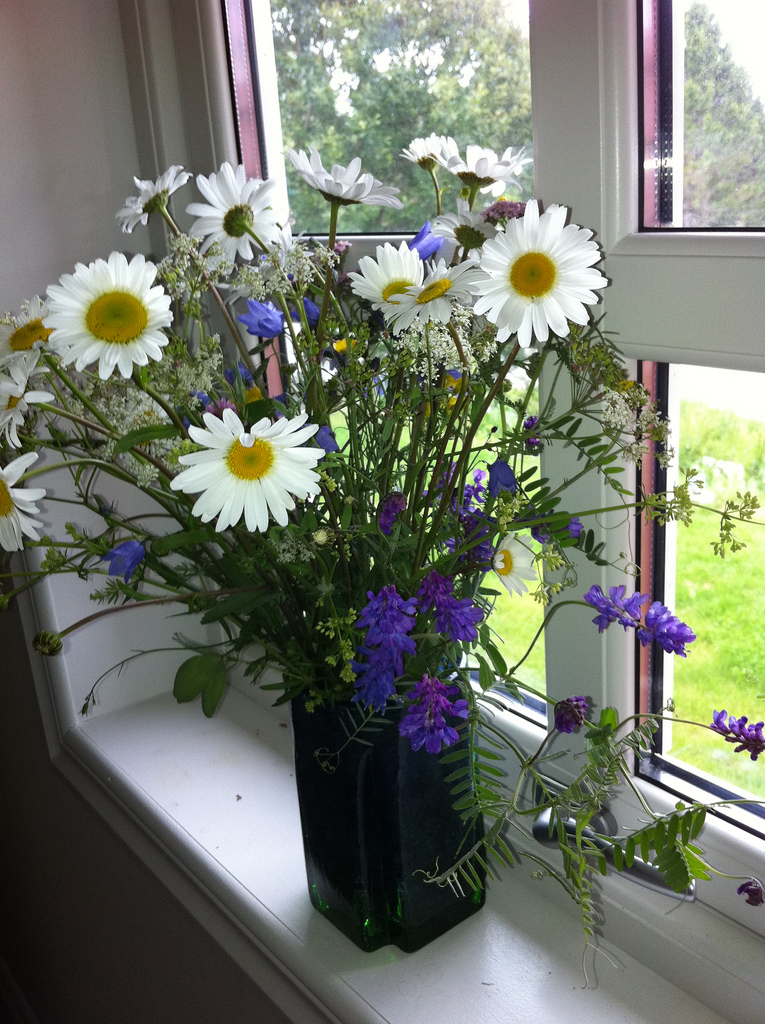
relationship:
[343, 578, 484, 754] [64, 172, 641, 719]
flowers are on plant